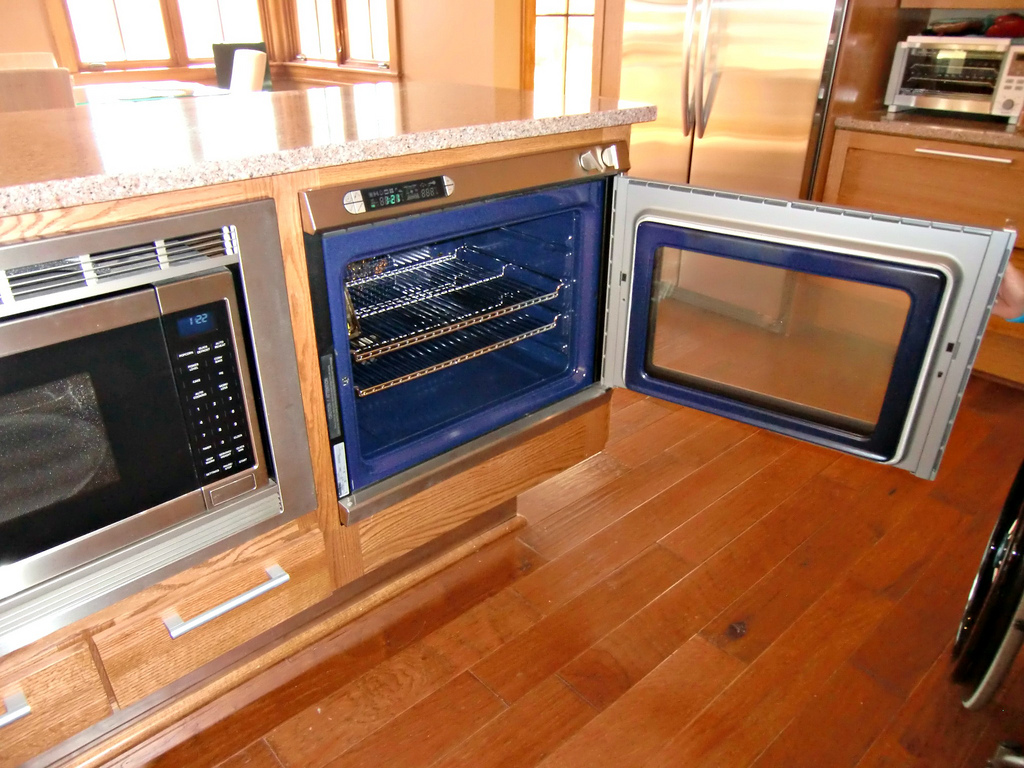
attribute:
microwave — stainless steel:
[13, 194, 338, 655]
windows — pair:
[56, 1, 389, 94]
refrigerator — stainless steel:
[622, 6, 849, 199]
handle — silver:
[142, 568, 331, 642]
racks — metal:
[345, 250, 568, 387]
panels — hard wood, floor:
[114, 382, 1022, 763]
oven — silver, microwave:
[2, 177, 340, 670]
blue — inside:
[309, 179, 668, 534]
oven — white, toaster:
[870, 15, 1022, 139]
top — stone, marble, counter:
[6, 69, 663, 255]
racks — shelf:
[349, 241, 578, 416]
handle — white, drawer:
[149, 555, 318, 659]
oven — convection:
[298, 109, 1020, 529]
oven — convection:
[298, 135, 1018, 553]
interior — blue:
[313, 174, 640, 509]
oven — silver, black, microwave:
[6, 194, 372, 672]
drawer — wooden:
[62, 527, 406, 702]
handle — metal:
[155, 548, 294, 654]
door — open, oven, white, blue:
[609, 164, 1014, 493]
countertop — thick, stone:
[8, 68, 665, 226]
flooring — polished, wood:
[149, 306, 1022, 760]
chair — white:
[179, 23, 300, 116]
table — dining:
[10, 60, 244, 115]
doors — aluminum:
[607, 2, 854, 229]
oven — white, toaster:
[874, 17, 1022, 128]